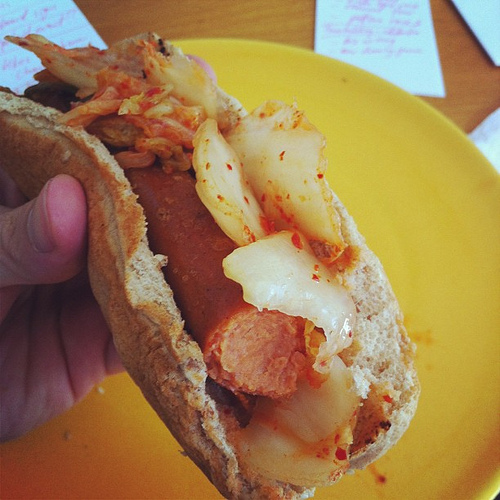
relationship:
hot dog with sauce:
[1, 42, 409, 473] [74, 73, 322, 310]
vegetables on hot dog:
[206, 112, 338, 306] [1, 42, 409, 473]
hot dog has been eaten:
[1, 42, 409, 473] [203, 335, 375, 460]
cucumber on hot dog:
[198, 110, 257, 241] [1, 42, 409, 473]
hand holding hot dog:
[1, 182, 124, 442] [1, 42, 409, 473]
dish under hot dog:
[222, 38, 498, 344] [1, 42, 409, 473]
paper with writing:
[337, 0, 444, 89] [342, 8, 425, 57]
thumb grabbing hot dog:
[5, 175, 86, 299] [1, 42, 409, 473]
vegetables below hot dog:
[206, 112, 338, 306] [1, 42, 409, 473]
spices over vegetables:
[61, 47, 189, 146] [206, 112, 338, 306]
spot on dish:
[363, 467, 394, 489] [222, 38, 498, 344]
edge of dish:
[249, 62, 445, 89] [222, 38, 498, 344]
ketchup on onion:
[39, 28, 174, 135] [206, 112, 338, 306]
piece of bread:
[152, 380, 213, 450] [94, 210, 192, 406]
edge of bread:
[128, 288, 189, 362] [94, 210, 192, 406]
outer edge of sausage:
[181, 260, 254, 389] [211, 302, 301, 388]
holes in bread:
[371, 311, 396, 355] [94, 210, 192, 406]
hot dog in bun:
[1, 42, 409, 473] [154, 313, 388, 471]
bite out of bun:
[203, 335, 375, 460] [154, 313, 388, 471]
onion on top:
[206, 112, 338, 306] [94, 71, 307, 319]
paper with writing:
[26, 0, 88, 34] [1, 8, 35, 24]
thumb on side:
[5, 175, 86, 299] [5, 188, 19, 400]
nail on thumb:
[27, 187, 52, 249] [5, 175, 86, 299]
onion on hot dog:
[169, 77, 312, 297] [1, 42, 409, 473]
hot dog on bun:
[1, 42, 409, 473] [154, 313, 388, 471]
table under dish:
[3, 0, 498, 131] [222, 38, 498, 344]